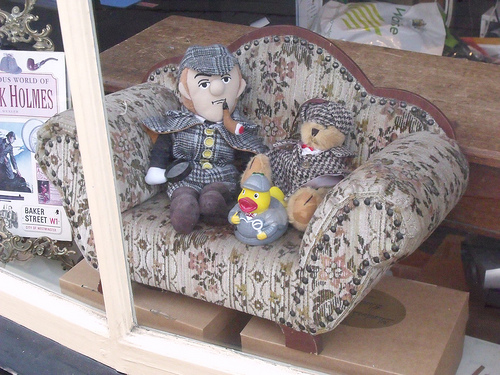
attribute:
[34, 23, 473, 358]
couch — floral, upholstered, toy, small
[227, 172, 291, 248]
rubber ducky — detective, yellow, existing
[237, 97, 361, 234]
bear — teddy bear, dr. watson, plush, ted bear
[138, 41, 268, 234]
sherlock holmes — doll, toy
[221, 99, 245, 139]
pipe — felt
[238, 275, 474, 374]
box — cardboard, large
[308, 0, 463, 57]
bag — plastic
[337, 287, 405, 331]
sticker — gold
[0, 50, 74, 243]
book — sherlock holmes, on side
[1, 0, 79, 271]
book holder — silver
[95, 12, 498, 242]
desk — wood, wooden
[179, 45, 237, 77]
hat — deerstalker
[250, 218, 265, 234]
magnifying glass — tiny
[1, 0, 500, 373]
photo — advertisement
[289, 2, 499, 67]
clutter — in background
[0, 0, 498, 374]
window — store front